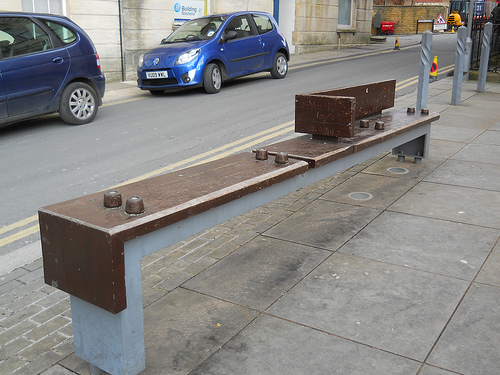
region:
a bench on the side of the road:
[73, 155, 293, 195]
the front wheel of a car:
[202, 66, 226, 90]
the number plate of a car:
[145, 70, 166, 81]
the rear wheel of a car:
[274, 53, 290, 75]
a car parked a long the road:
[138, 25, 293, 89]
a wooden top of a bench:
[111, 173, 266, 210]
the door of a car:
[231, 20, 262, 71]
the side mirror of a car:
[225, 31, 236, 39]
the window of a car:
[253, 15, 275, 32]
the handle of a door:
[48, 58, 65, 65]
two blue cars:
[3, 5, 303, 138]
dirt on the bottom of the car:
[1, 99, 64, 124]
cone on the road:
[428, 53, 442, 84]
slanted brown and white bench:
[25, 77, 443, 372]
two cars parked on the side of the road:
[0, 2, 298, 144]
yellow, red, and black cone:
[428, 53, 440, 79]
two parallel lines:
[1, 206, 38, 254]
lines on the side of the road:
[3, 47, 477, 261]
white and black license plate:
[143, 65, 175, 84]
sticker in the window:
[203, 27, 214, 37]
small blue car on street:
[137, 10, 304, 88]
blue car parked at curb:
[130, 0, 291, 100]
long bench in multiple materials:
[34, 77, 444, 374]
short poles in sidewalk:
[418, 21, 493, 112]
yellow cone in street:
[428, 54, 443, 85]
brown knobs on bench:
[95, 178, 145, 218]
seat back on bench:
[295, 80, 402, 140]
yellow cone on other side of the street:
[393, 37, 407, 52]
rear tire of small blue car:
[53, 75, 101, 126]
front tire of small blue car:
[201, 62, 226, 94]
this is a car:
[0, 7, 122, 131]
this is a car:
[143, 0, 299, 102]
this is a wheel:
[61, 71, 98, 131]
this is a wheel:
[205, 56, 224, 98]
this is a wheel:
[263, 52, 296, 77]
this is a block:
[284, 240, 476, 367]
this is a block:
[351, 198, 484, 291]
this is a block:
[429, 150, 496, 246]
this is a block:
[160, 265, 275, 370]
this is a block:
[282, 183, 401, 265]